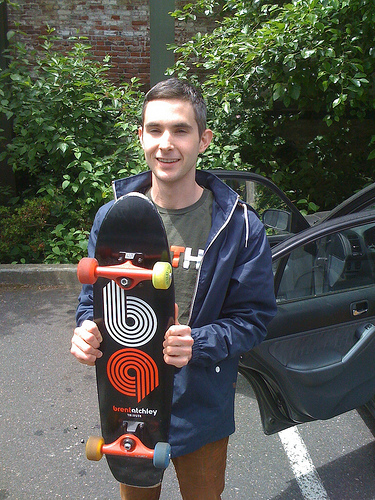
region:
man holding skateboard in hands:
[86, 68, 259, 367]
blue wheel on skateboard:
[148, 433, 174, 470]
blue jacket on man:
[184, 209, 281, 330]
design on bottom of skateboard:
[98, 280, 162, 408]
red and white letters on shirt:
[164, 241, 204, 276]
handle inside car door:
[331, 332, 370, 371]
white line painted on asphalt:
[278, 436, 327, 484]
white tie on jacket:
[232, 206, 253, 252]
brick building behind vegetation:
[89, 40, 139, 98]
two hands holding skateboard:
[68, 315, 188, 375]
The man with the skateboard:
[66, 74, 280, 498]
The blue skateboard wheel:
[151, 441, 174, 471]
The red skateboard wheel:
[75, 255, 100, 289]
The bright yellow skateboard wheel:
[150, 261, 173, 290]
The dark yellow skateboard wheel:
[83, 433, 105, 462]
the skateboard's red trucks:
[96, 261, 156, 463]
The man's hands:
[64, 301, 194, 374]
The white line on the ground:
[277, 422, 331, 498]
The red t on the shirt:
[171, 243, 186, 268]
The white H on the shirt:
[180, 239, 204, 272]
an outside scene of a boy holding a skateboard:
[0, 0, 374, 499]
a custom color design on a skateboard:
[76, 191, 175, 488]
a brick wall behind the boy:
[0, 0, 150, 90]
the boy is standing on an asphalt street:
[0, 285, 70, 499]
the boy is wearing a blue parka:
[76, 169, 274, 454]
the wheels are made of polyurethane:
[77, 256, 97, 284]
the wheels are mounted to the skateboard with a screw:
[76, 256, 171, 289]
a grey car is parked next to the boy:
[277, 178, 373, 498]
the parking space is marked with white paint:
[275, 434, 335, 498]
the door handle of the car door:
[351, 299, 369, 317]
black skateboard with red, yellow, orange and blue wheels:
[75, 185, 178, 493]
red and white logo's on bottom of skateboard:
[99, 279, 163, 405]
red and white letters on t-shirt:
[169, 241, 205, 272]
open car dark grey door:
[234, 211, 372, 439]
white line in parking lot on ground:
[275, 440, 335, 498]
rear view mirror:
[259, 203, 293, 231]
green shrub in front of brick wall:
[219, 2, 372, 161]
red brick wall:
[7, 1, 146, 31]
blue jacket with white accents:
[74, 171, 278, 459]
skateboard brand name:
[103, 403, 159, 421]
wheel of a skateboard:
[155, 449, 173, 462]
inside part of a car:
[306, 338, 326, 355]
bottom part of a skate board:
[125, 302, 137, 355]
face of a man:
[150, 100, 192, 168]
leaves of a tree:
[301, 36, 337, 75]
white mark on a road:
[301, 467, 310, 473]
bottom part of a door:
[257, 420, 285, 439]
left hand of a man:
[170, 331, 190, 359]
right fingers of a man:
[81, 333, 91, 355]